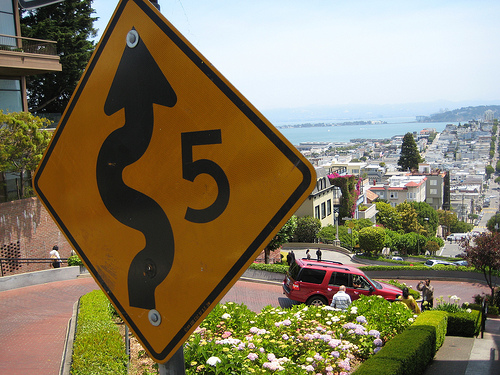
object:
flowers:
[330, 350, 341, 358]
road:
[0, 273, 499, 375]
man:
[330, 285, 352, 310]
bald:
[338, 285, 347, 292]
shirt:
[49, 249, 62, 263]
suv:
[279, 258, 403, 311]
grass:
[69, 291, 123, 374]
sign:
[30, 0, 316, 362]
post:
[150, 342, 190, 374]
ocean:
[270, 122, 471, 149]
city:
[249, 118, 499, 270]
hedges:
[346, 308, 484, 375]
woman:
[47, 244, 65, 268]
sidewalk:
[0, 263, 89, 286]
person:
[416, 278, 436, 313]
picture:
[0, 0, 500, 375]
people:
[315, 248, 323, 262]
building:
[1, 1, 63, 200]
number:
[179, 126, 233, 224]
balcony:
[1, 31, 65, 76]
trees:
[355, 224, 387, 258]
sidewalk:
[276, 246, 348, 264]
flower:
[207, 355, 222, 368]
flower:
[250, 325, 267, 339]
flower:
[218, 337, 244, 349]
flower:
[263, 358, 284, 369]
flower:
[346, 322, 366, 336]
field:
[208, 119, 500, 372]